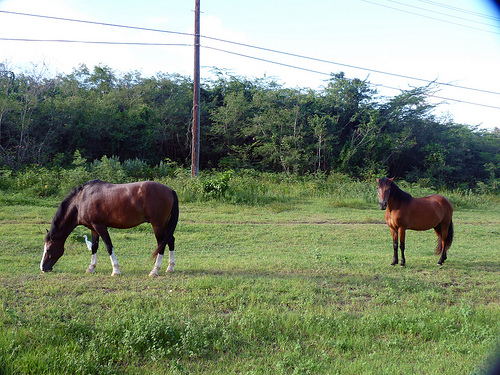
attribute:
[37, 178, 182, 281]
horse — brown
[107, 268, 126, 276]
foot — socked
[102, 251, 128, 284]
sock — white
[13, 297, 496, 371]
grass — green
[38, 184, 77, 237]
mane — black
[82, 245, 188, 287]
hooves — white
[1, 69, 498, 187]
trees — tall